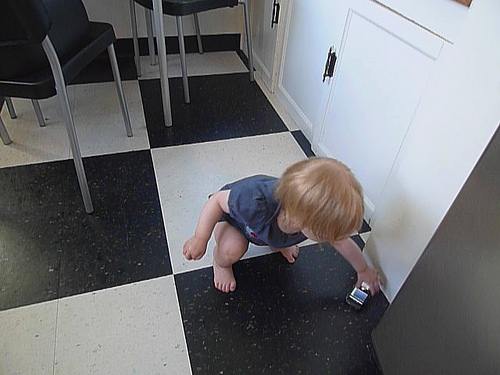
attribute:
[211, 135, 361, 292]
kid — blonde, young, little, sitting, white, playing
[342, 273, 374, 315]
toy — car, small, blue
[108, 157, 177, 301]
floor — white, black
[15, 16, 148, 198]
chair — black, silver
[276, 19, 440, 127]
door — white, closed